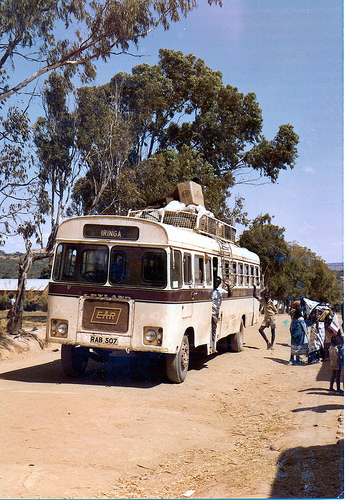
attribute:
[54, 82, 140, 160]
leaves —  green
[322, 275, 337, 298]
leaves —  green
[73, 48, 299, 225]
leaves —  green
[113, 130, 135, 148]
leaves —  green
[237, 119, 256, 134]
leaves —  green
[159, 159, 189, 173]
leaves — green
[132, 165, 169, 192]
green leaves —  green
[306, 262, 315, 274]
leaves —  green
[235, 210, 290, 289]
leaves — green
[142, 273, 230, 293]
bus —  old,  white,  passenger bus